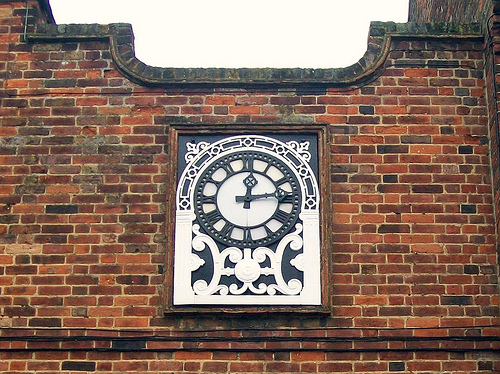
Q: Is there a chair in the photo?
A: No, there are no chairs.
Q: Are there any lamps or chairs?
A: No, there are no chairs or lamps.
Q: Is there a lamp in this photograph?
A: No, there are no lamps.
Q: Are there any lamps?
A: No, there are no lamps.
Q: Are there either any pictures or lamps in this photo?
A: No, there are no lamps or pictures.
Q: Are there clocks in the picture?
A: Yes, there is a clock.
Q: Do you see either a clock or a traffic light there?
A: Yes, there is a clock.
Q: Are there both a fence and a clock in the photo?
A: No, there is a clock but no fences.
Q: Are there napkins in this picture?
A: No, there are no napkins.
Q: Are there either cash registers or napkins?
A: No, there are no napkins or cash registers.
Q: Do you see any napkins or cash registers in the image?
A: No, there are no napkins or cash registers.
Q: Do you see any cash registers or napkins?
A: No, there are no napkins or cash registers.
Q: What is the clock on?
A: The clock is on the wall.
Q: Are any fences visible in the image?
A: No, there are no fences.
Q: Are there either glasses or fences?
A: No, there are no fences or glasses.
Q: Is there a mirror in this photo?
A: No, there are no mirrors.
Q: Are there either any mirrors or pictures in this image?
A: No, there are no mirrors or pictures.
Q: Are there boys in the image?
A: No, there are no boys.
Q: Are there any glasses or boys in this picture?
A: No, there are no boys or glasses.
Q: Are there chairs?
A: No, there are no chairs.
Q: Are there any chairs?
A: No, there are no chairs.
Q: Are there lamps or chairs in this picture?
A: No, there are no chairs or lamps.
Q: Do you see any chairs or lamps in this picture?
A: No, there are no chairs or lamps.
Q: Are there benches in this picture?
A: No, there are no benches.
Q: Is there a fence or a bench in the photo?
A: No, there are no benches or fences.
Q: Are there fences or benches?
A: No, there are no benches or fences.